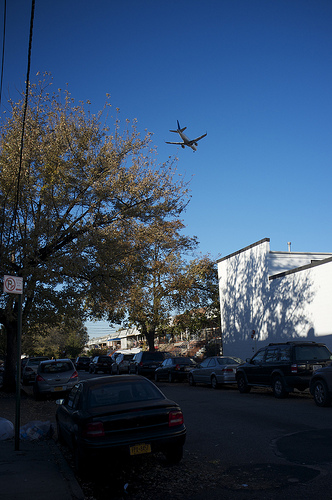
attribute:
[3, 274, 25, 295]
sign — red, white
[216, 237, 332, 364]
building — white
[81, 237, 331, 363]
buildings — in a row, lined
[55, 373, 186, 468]
car — parked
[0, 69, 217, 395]
tree — yellow-green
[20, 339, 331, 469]
cars — parked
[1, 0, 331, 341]
sky — blue, clear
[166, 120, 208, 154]
airplane — flying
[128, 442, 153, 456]
license plate — yellow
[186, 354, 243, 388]
car — silver